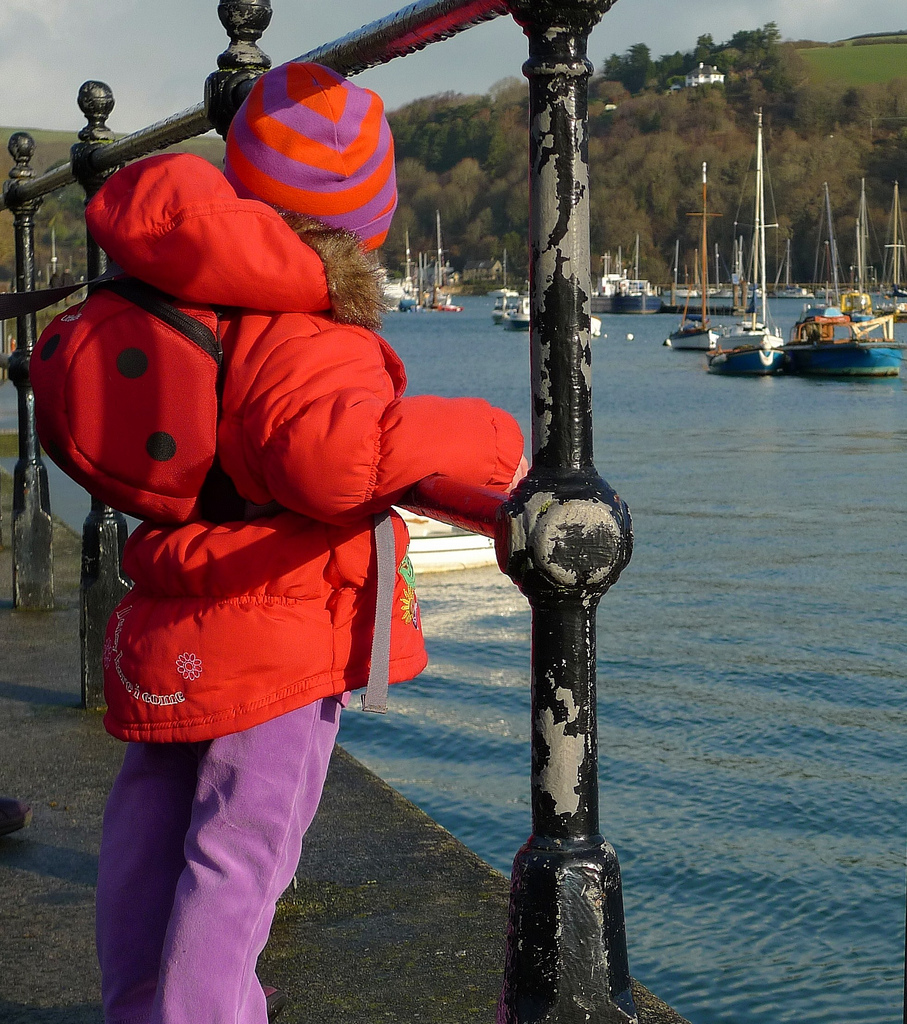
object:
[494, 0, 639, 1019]
metal railing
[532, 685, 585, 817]
chipped paint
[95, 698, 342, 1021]
purple pants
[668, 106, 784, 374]
sailboats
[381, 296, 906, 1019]
water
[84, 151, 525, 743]
jacket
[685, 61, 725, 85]
house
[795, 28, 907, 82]
hill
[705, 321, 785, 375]
boat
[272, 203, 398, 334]
fur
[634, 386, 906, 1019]
water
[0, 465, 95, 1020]
walkway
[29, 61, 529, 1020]
girl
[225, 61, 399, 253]
hat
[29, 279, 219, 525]
backpack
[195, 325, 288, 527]
back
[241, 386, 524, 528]
coat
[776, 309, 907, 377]
sailboats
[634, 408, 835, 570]
water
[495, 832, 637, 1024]
railing